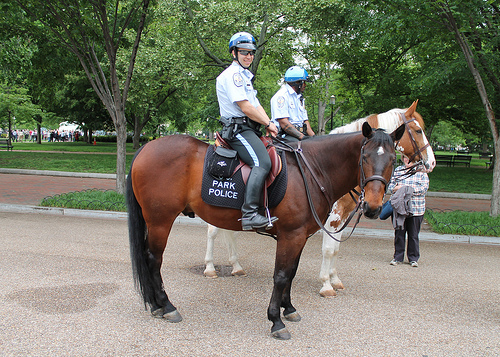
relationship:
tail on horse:
[122, 173, 148, 305] [124, 122, 406, 341]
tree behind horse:
[6, 2, 160, 194] [124, 122, 406, 341]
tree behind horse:
[6, 2, 160, 194] [201, 99, 438, 303]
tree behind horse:
[124, 2, 296, 139] [124, 122, 406, 341]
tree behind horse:
[124, 2, 296, 139] [201, 99, 438, 303]